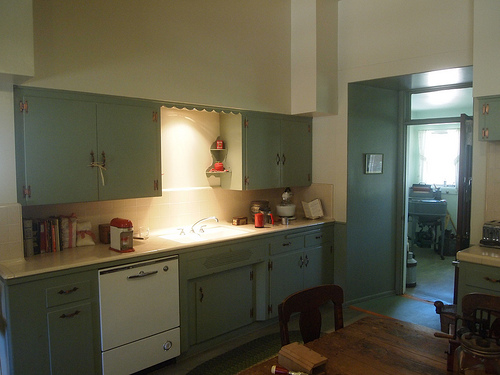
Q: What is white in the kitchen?
A: The walls.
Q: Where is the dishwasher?
A: In the kitchen.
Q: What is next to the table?
A: A chair.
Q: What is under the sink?
A: A cabinet.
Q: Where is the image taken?
A: Kitchen.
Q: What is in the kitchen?
A: Table.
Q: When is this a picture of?
A: A kitchen.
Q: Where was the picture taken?
A: Inside the house.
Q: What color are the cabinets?
A: Blue.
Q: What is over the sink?
A: A light.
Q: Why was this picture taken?
A: To show off the room.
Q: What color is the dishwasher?
A: White.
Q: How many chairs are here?
A: One.